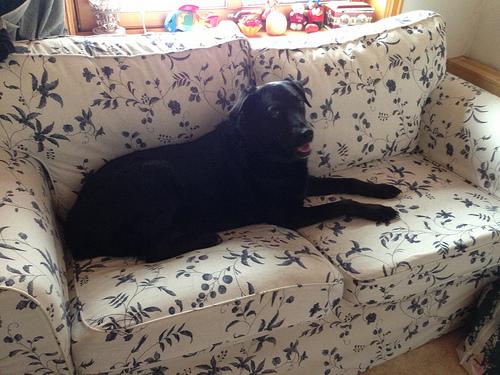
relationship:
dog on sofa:
[58, 82, 405, 268] [3, 0, 498, 373]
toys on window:
[167, 1, 349, 40] [65, 2, 403, 29]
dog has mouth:
[58, 82, 405, 268] [292, 135, 314, 161]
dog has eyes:
[58, 82, 405, 268] [268, 98, 309, 122]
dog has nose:
[58, 82, 405, 268] [293, 125, 314, 143]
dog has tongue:
[58, 82, 405, 268] [300, 144, 311, 154]